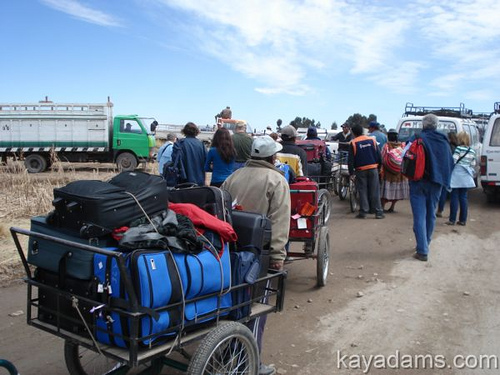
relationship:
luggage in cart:
[25, 169, 270, 349] [10, 225, 288, 374]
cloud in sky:
[38, 0, 129, 34] [1, 0, 500, 132]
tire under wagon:
[185, 320, 262, 374] [10, 225, 288, 374]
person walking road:
[446, 133, 477, 226] [261, 180, 500, 374]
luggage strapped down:
[25, 169, 270, 349] [126, 190, 186, 357]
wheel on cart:
[185, 320, 262, 374] [10, 225, 288, 374]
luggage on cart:
[25, 169, 270, 349] [10, 225, 288, 374]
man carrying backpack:
[401, 114, 452, 261] [402, 137, 426, 181]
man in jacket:
[401, 114, 452, 261] [411, 133, 454, 187]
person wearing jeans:
[446, 133, 477, 226] [449, 188, 468, 223]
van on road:
[477, 103, 499, 203] [261, 180, 500, 374]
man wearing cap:
[219, 135, 292, 278] [251, 134, 283, 158]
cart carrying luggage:
[10, 225, 288, 374] [25, 169, 270, 349]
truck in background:
[1, 97, 157, 173] [2, 97, 499, 186]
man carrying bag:
[401, 114, 452, 261] [402, 137, 426, 181]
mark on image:
[335, 347, 500, 371] [0, 2, 499, 374]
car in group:
[398, 104, 481, 158] [394, 104, 499, 207]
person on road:
[446, 133, 477, 226] [261, 180, 500, 374]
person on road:
[347, 125, 386, 216] [261, 180, 500, 374]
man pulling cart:
[219, 135, 292, 278] [10, 225, 288, 374]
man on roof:
[106, 96, 115, 109] [0, 103, 113, 117]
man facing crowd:
[332, 122, 355, 165] [155, 112, 483, 283]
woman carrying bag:
[164, 122, 208, 187] [162, 157, 188, 187]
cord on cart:
[194, 228, 225, 293] [10, 225, 288, 374]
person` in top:
[446, 133, 477, 226] [453, 145, 477, 171]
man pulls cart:
[219, 135, 292, 278] [10, 225, 288, 374]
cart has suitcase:
[10, 225, 288, 374] [27, 213, 106, 278]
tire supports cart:
[185, 320, 262, 374] [10, 225, 288, 374]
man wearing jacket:
[219, 135, 292, 278] [219, 159, 293, 266]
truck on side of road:
[1, 97, 157, 173] [261, 180, 500, 374]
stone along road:
[358, 290, 364, 298] [261, 180, 500, 374]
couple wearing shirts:
[171, 122, 237, 189] [170, 137, 235, 184]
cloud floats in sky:
[38, 0, 129, 34] [1, 0, 500, 132]